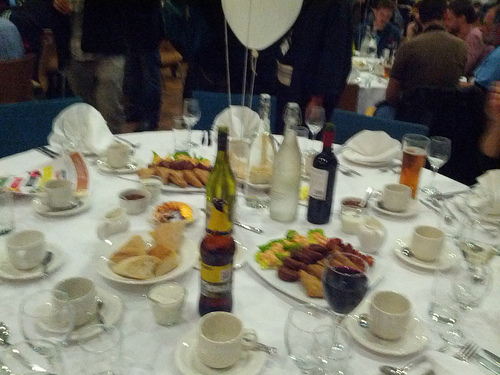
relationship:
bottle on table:
[309, 126, 337, 225] [1, 127, 499, 374]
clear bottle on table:
[272, 104, 300, 221] [1, 127, 499, 374]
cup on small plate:
[366, 297, 411, 335] [345, 311, 431, 355]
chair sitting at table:
[326, 106, 423, 147] [1, 127, 499, 374]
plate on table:
[95, 232, 195, 285] [1, 127, 499, 374]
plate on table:
[174, 326, 270, 374] [1, 127, 499, 374]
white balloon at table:
[223, 1, 303, 52] [1, 127, 499, 374]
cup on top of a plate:
[53, 279, 98, 321] [43, 297, 118, 337]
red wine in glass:
[321, 277, 366, 310] [323, 253, 361, 353]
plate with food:
[95, 232, 195, 285] [119, 233, 177, 272]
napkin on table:
[347, 133, 401, 165] [1, 127, 499, 374]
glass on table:
[323, 253, 361, 353] [1, 127, 499, 374]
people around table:
[3, 6, 500, 111] [1, 127, 499, 374]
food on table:
[119, 233, 177, 272] [1, 127, 499, 374]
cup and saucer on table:
[377, 179, 419, 219] [1, 127, 499, 374]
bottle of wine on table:
[309, 126, 337, 225] [1, 127, 499, 374]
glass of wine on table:
[323, 253, 361, 353] [1, 127, 499, 374]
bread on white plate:
[119, 233, 177, 272] [95, 232, 195, 285]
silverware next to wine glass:
[388, 345, 472, 371] [323, 253, 361, 353]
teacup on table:
[204, 313, 249, 368] [1, 127, 499, 374]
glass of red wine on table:
[323, 253, 361, 353] [1, 127, 499, 374]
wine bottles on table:
[203, 97, 352, 319] [1, 127, 499, 374]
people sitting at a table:
[3, 6, 500, 111] [329, 38, 420, 112]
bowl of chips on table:
[148, 201, 198, 224] [1, 127, 499, 374]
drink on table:
[281, 305, 350, 366] [1, 127, 499, 374]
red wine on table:
[321, 277, 366, 310] [1, 127, 499, 374]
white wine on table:
[272, 104, 300, 221] [1, 127, 499, 374]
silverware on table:
[388, 345, 472, 371] [1, 127, 499, 374]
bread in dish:
[119, 233, 177, 272] [95, 232, 195, 285]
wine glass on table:
[427, 138, 446, 191] [1, 127, 499, 374]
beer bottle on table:
[197, 196, 237, 310] [1, 127, 499, 374]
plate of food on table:
[264, 227, 369, 301] [1, 127, 499, 374]